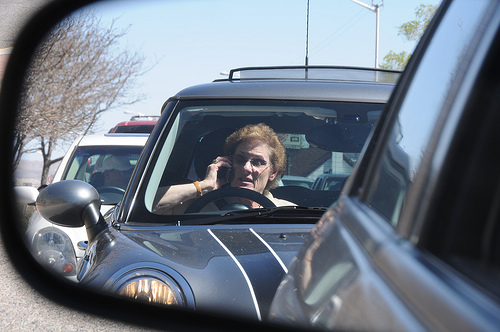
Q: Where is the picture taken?
A: Car.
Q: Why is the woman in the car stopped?
A: Traffic.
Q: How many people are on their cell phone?
A: One.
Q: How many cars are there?
A: Four.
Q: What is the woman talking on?
A: Cell phone.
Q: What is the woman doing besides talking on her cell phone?
A: Driving.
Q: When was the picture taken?
A: Daytime.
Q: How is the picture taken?
A: Looking in a mirror.